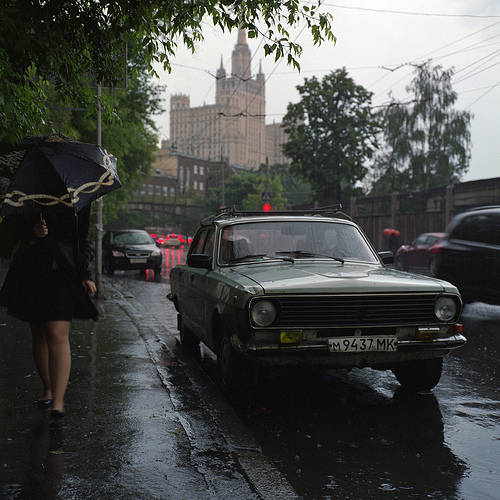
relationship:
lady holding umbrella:
[0, 201, 99, 418] [7, 142, 124, 220]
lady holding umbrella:
[4, 157, 96, 429] [4, 126, 124, 228]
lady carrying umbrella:
[0, 201, 99, 418] [10, 78, 155, 225]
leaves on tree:
[278, 66, 387, 201] [281, 65, 386, 202]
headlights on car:
[242, 293, 462, 329] [165, 203, 469, 397]